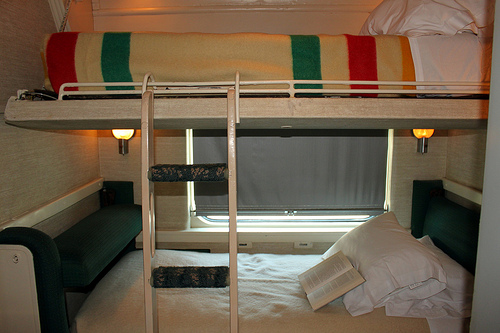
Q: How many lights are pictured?
A: Two.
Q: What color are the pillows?
A: White.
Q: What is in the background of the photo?
A: Curtain, daylight.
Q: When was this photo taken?
A: Daytime.